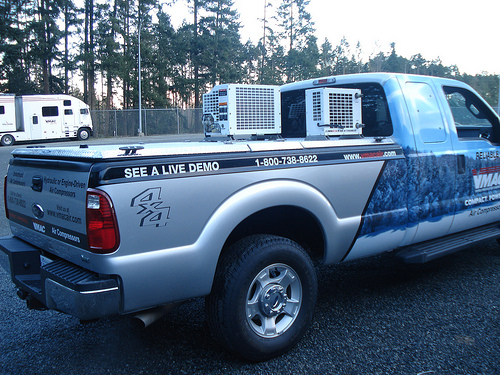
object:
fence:
[90, 108, 203, 136]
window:
[441, 83, 497, 143]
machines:
[306, 87, 368, 141]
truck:
[1, 64, 498, 368]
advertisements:
[121, 147, 399, 179]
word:
[160, 162, 186, 181]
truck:
[0, 69, 499, 360]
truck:
[0, 69, 493, 363]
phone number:
[252, 154, 321, 166]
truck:
[1, 68, 498, 365]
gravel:
[0, 329, 196, 374]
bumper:
[3, 267, 125, 323]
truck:
[13, 63, 500, 369]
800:
[259, 157, 282, 167]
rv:
[1, 92, 96, 146]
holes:
[234, 104, 246, 108]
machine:
[201, 80, 284, 143]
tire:
[209, 231, 322, 367]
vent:
[196, 81, 230, 143]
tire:
[219, 232, 323, 357]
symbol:
[129, 185, 172, 228]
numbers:
[248, 154, 321, 166]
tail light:
[86, 187, 117, 253]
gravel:
[330, 296, 489, 367]